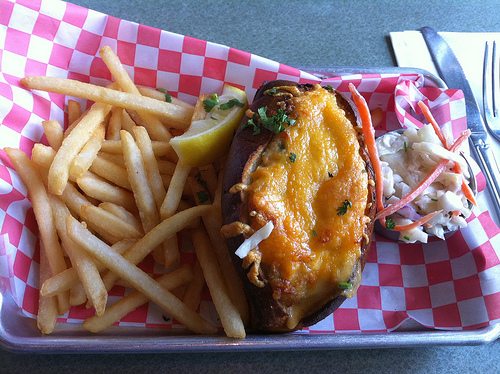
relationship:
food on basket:
[370, 123, 470, 243] [1, 65, 500, 356]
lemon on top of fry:
[165, 85, 251, 166] [187, 225, 245, 342]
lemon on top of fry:
[165, 85, 251, 166] [104, 196, 215, 290]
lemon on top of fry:
[165, 85, 251, 166] [114, 125, 158, 230]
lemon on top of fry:
[165, 85, 251, 166] [21, 69, 188, 130]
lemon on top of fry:
[165, 85, 251, 166] [8, 145, 68, 275]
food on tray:
[370, 123, 470, 243] [6, 74, 498, 354]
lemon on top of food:
[169, 82, 249, 164] [370, 123, 470, 243]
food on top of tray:
[370, 123, 470, 243] [6, 74, 498, 354]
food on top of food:
[370, 123, 470, 243] [370, 123, 470, 243]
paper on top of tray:
[2, 7, 491, 329] [6, 74, 498, 354]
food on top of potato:
[370, 123, 470, 243] [225, 80, 372, 332]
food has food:
[370, 123, 470, 243] [370, 123, 470, 243]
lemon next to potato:
[169, 82, 249, 164] [225, 80, 372, 332]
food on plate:
[370, 123, 470, 243] [5, 36, 499, 349]